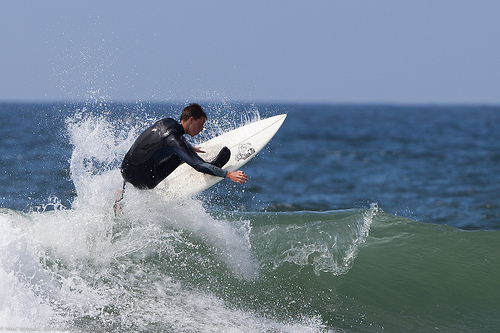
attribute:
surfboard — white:
[63, 104, 294, 241]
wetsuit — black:
[115, 119, 222, 195]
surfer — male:
[110, 103, 249, 204]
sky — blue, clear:
[1, 2, 500, 104]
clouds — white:
[6, 7, 500, 58]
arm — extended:
[167, 137, 244, 181]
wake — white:
[6, 168, 280, 332]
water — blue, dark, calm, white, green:
[1, 103, 499, 333]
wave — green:
[0, 212, 499, 333]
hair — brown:
[181, 103, 207, 118]